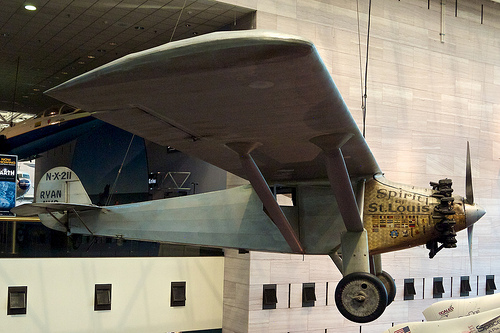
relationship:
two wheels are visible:
[252, 244, 424, 333] [309, 294, 324, 333]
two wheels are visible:
[333, 269, 396, 324] [372, 291, 398, 333]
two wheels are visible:
[333, 269, 396, 324] [302, 239, 416, 333]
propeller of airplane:
[443, 152, 479, 280] [120, 110, 480, 243]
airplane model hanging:
[60, 202, 473, 317] [70, 109, 488, 289]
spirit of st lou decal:
[372, 176, 432, 241] [369, 145, 478, 280]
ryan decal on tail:
[29, 180, 59, 200] [29, 100, 148, 320]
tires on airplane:
[334, 265, 394, 316] [7, 28, 485, 325]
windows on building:
[0, 276, 190, 314] [6, 2, 484, 328]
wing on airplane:
[41, 25, 386, 190] [7, 28, 485, 325]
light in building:
[17, 2, 38, 12] [6, 2, 484, 328]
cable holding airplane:
[351, 1, 376, 139] [7, 28, 485, 325]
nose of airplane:
[15, 170, 29, 199] [18, 174, 34, 200]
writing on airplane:
[366, 202, 428, 215] [7, 28, 485, 325]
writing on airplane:
[36, 184, 67, 200] [7, 28, 485, 325]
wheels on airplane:
[334, 265, 395, 325] [7, 28, 485, 325]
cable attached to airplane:
[351, 1, 376, 139] [7, 28, 485, 325]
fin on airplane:
[27, 166, 92, 201] [7, 28, 485, 325]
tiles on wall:
[394, 63, 439, 116] [227, 1, 484, 329]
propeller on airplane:
[463, 140, 476, 275] [7, 28, 485, 325]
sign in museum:
[3, 148, 19, 209] [3, 1, 484, 326]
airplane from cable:
[7, 28, 485, 325] [352, 2, 375, 142]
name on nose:
[363, 186, 438, 221] [363, 166, 483, 256]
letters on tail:
[36, 187, 68, 199] [31, 164, 97, 204]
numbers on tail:
[43, 170, 75, 182] [31, 164, 97, 204]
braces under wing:
[222, 127, 363, 254] [41, 25, 386, 190]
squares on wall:
[3, 276, 201, 316] [3, 243, 485, 330]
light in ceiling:
[17, 2, 38, 12] [0, 0, 269, 128]